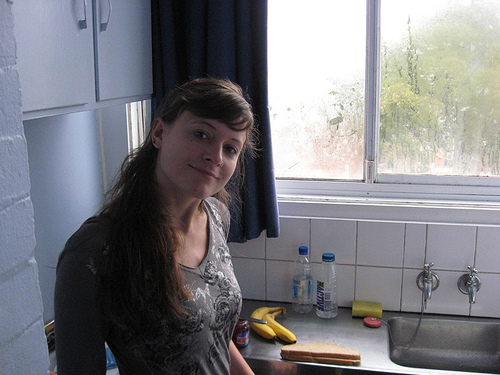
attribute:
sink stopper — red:
[360, 314, 384, 329]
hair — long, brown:
[128, 164, 173, 279]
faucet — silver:
[456, 263, 482, 308]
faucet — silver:
[407, 250, 439, 307]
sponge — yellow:
[343, 301, 400, 325]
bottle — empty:
[314, 252, 339, 320]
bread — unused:
[279, 341, 361, 368]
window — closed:
[266, 5, 498, 185]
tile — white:
[354, 221, 407, 268]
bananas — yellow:
[252, 300, 296, 342]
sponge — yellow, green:
[349, 296, 387, 321]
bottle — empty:
[308, 260, 360, 321]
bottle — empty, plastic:
[314, 250, 341, 321]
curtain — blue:
[149, 0, 281, 244]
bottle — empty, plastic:
[290, 242, 315, 316]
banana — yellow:
[248, 300, 285, 340]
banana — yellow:
[262, 305, 300, 343]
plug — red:
[362, 314, 381, 330]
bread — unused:
[277, 351, 362, 367]